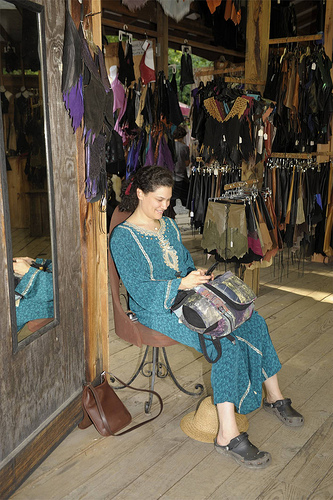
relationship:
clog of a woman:
[211, 430, 272, 470] [106, 163, 306, 469]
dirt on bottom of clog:
[212, 447, 272, 466] [211, 430, 272, 470]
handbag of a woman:
[172, 269, 257, 364] [106, 163, 306, 469]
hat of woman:
[178, 394, 253, 445] [106, 163, 306, 469]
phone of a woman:
[205, 259, 221, 280] [106, 163, 306, 469]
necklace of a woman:
[133, 207, 164, 234] [106, 163, 306, 469]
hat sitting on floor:
[178, 394, 253, 445] [0, 215, 332, 500]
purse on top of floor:
[77, 370, 168, 438] [0, 215, 332, 500]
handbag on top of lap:
[172, 269, 257, 364] [130, 298, 257, 353]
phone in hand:
[205, 259, 221, 280] [177, 268, 213, 295]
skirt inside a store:
[195, 197, 252, 262] [1, 0, 330, 499]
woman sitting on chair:
[106, 163, 306, 469] [95, 199, 206, 414]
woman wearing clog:
[106, 163, 306, 469] [211, 430, 272, 470]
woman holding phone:
[106, 163, 306, 469] [205, 259, 221, 280]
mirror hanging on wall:
[1, 1, 61, 359] [1, 0, 111, 499]